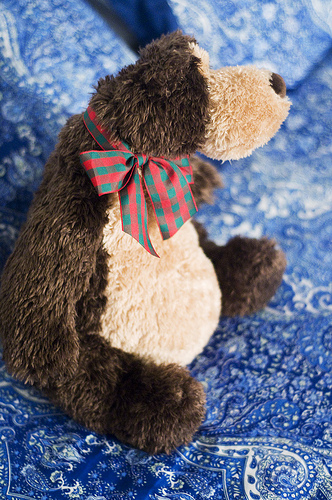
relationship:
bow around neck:
[80, 111, 203, 247] [66, 97, 210, 241]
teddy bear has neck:
[5, 40, 291, 452] [66, 97, 210, 241]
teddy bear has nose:
[5, 40, 291, 452] [268, 72, 290, 108]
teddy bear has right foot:
[5, 40, 291, 452] [98, 351, 209, 462]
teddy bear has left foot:
[5, 40, 291, 452] [216, 235, 282, 323]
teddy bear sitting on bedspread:
[5, 40, 291, 452] [12, 19, 326, 487]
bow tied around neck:
[80, 111, 203, 247] [66, 97, 210, 241]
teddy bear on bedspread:
[5, 40, 291, 452] [12, 19, 326, 487]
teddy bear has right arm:
[5, 40, 291, 452] [3, 223, 88, 395]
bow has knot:
[80, 111, 203, 247] [131, 150, 153, 171]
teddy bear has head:
[5, 40, 291, 452] [112, 35, 290, 167]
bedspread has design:
[12, 19, 326, 487] [217, 355, 327, 499]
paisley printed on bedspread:
[204, 345, 323, 497] [12, 19, 326, 487]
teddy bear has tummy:
[5, 40, 291, 452] [113, 253, 221, 359]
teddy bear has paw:
[5, 40, 291, 452] [161, 377, 199, 441]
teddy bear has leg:
[5, 40, 291, 452] [142, 246, 282, 460]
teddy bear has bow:
[5, 40, 291, 452] [80, 111, 203, 247]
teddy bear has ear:
[5, 40, 291, 452] [134, 47, 189, 94]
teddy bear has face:
[5, 40, 291, 452] [185, 41, 294, 167]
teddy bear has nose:
[5, 40, 291, 452] [268, 72, 283, 97]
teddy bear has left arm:
[5, 40, 291, 452] [194, 153, 226, 212]